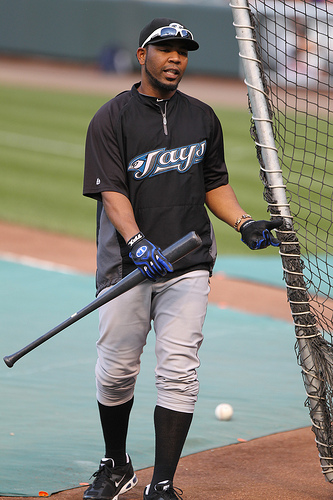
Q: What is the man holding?
A: A bat.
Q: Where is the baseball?
A: On the tarp.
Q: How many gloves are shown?
A: Two.